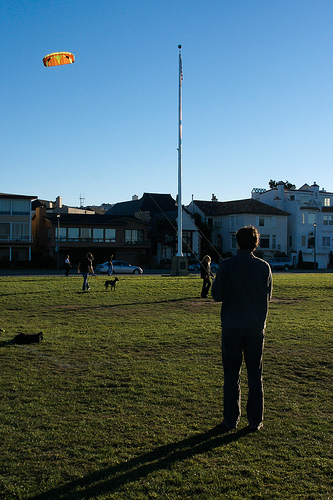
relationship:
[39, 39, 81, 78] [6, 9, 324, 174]
parachute flying in sky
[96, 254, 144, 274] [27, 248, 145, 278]
car parked on side of road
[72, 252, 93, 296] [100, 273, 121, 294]
man walking dog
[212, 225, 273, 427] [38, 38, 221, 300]
person flying flying a kite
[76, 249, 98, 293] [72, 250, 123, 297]
person walking walking pet dog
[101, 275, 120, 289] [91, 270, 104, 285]
dog on orange leash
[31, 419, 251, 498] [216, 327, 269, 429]
shadow from person's legs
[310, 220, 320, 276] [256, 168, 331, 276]
street light in front of apartments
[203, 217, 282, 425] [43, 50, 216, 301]
man flying flying the kite